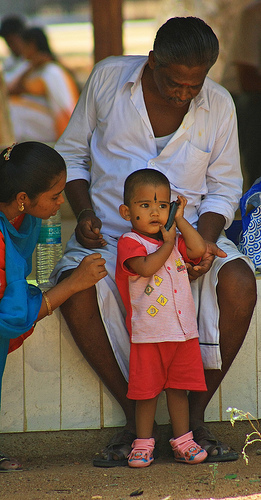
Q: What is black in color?
A: The sandals.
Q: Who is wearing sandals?
A: The man.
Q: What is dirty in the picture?
A: The ground.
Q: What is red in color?
A: The baby's shorts.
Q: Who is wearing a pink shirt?
A: The baby.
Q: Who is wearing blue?
A: The woman.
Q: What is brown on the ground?
A: Dirt.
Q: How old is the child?
A: Young.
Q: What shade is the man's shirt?
A: White.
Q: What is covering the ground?
A: Dirt.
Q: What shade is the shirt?
A: Red.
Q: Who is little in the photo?
A: A kid.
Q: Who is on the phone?
A: The kid.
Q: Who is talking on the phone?
A: Small child in red.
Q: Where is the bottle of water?
A: Next to the man.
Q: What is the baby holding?
A: Cellphone.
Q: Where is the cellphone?
A: Baby's hands.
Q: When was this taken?
A: Day time.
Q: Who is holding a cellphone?
A: Baby.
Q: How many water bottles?
A: One.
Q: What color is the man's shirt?
A: White.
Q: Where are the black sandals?
A: Man's feet.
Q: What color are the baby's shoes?
A: Pink.